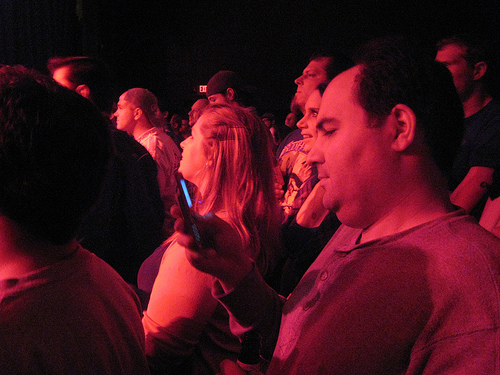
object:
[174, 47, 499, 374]
man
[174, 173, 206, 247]
phone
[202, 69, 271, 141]
man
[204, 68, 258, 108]
cap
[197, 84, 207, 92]
sign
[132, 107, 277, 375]
woman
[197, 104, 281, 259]
hair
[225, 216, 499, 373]
shirt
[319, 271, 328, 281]
button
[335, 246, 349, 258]
button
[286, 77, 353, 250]
woman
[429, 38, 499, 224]
person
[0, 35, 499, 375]
group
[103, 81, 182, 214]
person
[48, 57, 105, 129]
person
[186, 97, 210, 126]
person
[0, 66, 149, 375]
person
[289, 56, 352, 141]
person